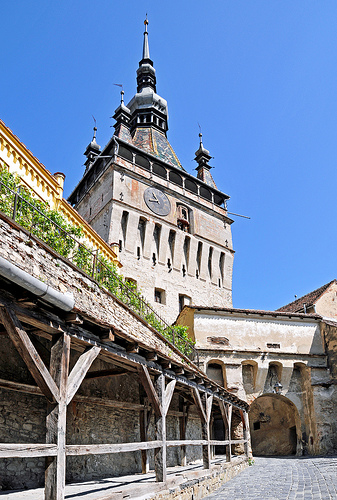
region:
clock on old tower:
[141, 184, 171, 217]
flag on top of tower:
[114, 81, 125, 89]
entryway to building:
[243, 392, 307, 454]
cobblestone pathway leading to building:
[210, 454, 335, 499]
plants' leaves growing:
[0, 166, 197, 357]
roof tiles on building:
[276, 281, 333, 314]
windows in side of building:
[123, 276, 191, 313]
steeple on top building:
[125, 9, 184, 167]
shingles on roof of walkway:
[0, 222, 199, 377]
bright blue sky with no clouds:
[0, 1, 334, 310]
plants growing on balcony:
[0, 160, 201, 367]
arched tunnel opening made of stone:
[247, 389, 304, 461]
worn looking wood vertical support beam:
[0, 303, 106, 497]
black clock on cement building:
[142, 181, 174, 217]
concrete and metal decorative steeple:
[125, 7, 175, 116]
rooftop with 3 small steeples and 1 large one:
[76, 9, 220, 193]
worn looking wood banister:
[0, 435, 251, 461]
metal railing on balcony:
[0, 179, 202, 373]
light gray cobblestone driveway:
[187, 453, 335, 498]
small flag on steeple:
[111, 81, 128, 104]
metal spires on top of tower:
[74, 0, 228, 184]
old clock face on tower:
[136, 181, 176, 214]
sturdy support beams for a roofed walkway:
[0, 295, 248, 497]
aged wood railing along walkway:
[4, 429, 260, 481]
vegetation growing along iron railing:
[0, 164, 194, 355]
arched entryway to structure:
[242, 393, 315, 462]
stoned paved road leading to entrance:
[201, 453, 335, 497]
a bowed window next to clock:
[170, 201, 197, 234]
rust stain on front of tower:
[115, 159, 148, 211]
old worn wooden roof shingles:
[1, 223, 215, 372]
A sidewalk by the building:
[212, 456, 336, 498]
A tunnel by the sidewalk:
[249, 393, 299, 451]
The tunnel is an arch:
[248, 394, 297, 452]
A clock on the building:
[143, 186, 170, 213]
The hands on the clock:
[149, 191, 159, 201]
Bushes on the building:
[2, 170, 193, 353]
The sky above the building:
[1, 1, 336, 311]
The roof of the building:
[271, 280, 332, 311]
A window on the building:
[154, 289, 164, 301]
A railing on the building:
[0, 184, 198, 364]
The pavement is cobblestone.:
[265, 470, 323, 495]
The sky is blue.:
[264, 142, 317, 202]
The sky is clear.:
[255, 176, 309, 216]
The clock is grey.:
[143, 185, 171, 216]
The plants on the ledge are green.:
[40, 211, 84, 256]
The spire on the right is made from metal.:
[194, 123, 205, 142]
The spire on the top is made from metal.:
[141, 9, 150, 32]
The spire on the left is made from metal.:
[114, 81, 126, 100]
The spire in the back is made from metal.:
[87, 114, 98, 138]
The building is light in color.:
[249, 394, 308, 453]